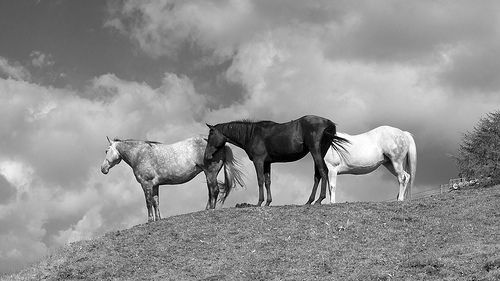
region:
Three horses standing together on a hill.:
[96, 112, 416, 238]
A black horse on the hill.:
[202, 110, 333, 206]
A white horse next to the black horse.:
[308, 123, 416, 200]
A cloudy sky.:
[5, 6, 497, 196]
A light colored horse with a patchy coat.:
[96, 125, 226, 210]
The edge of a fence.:
[395, 175, 480, 198]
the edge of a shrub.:
[445, 107, 498, 187]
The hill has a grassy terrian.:
[65, 225, 481, 273]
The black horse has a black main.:
[217, 120, 257, 143]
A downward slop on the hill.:
[2, 221, 150, 280]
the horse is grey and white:
[98, 114, 216, 219]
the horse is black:
[206, 113, 334, 210]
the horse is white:
[338, 126, 430, 212]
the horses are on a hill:
[113, 95, 415, 218]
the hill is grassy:
[136, 218, 483, 280]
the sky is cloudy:
[121, 21, 466, 110]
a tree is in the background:
[455, 135, 499, 165]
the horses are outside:
[85, 108, 431, 220]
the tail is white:
[406, 144, 425, 188]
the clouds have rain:
[198, 11, 475, 114]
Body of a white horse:
[315, 119, 415, 204]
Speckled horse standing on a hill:
[83, 126, 235, 221]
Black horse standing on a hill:
[190, 113, 345, 211]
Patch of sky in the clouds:
[2, 2, 240, 107]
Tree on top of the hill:
[445, 101, 498, 191]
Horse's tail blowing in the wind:
[220, 152, 246, 202]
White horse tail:
[401, 134, 425, 198]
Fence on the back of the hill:
[376, 179, 473, 209]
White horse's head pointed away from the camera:
[92, 132, 127, 183]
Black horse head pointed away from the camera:
[192, 114, 244, 176]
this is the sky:
[16, 10, 75, 32]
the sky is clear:
[12, 10, 72, 36]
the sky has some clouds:
[181, 8, 486, 104]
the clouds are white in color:
[26, 116, 84, 205]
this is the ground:
[184, 219, 349, 264]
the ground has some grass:
[223, 209, 339, 269]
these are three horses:
[91, 111, 421, 209]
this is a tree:
[462, 115, 499, 183]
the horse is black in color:
[250, 125, 283, 135]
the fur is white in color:
[352, 136, 367, 156]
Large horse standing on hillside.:
[80, 119, 248, 235]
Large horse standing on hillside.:
[186, 94, 328, 191]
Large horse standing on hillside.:
[302, 103, 408, 177]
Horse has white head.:
[88, 136, 125, 178]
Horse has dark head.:
[198, 119, 255, 199]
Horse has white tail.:
[399, 128, 431, 203]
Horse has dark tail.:
[316, 114, 341, 169]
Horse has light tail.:
[213, 118, 242, 221]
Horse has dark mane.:
[212, 108, 274, 155]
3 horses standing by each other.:
[85, 88, 425, 210]